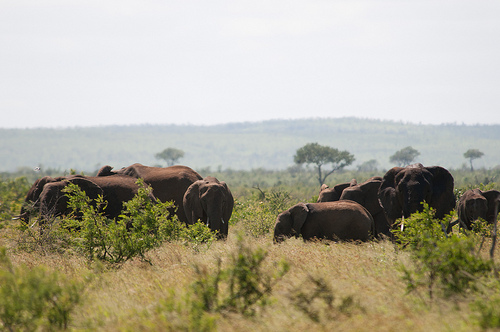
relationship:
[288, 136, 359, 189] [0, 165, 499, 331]
tree on savannah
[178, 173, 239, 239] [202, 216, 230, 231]
elephant has tusk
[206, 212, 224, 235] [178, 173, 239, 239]
trunk of elephant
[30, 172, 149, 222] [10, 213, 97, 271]
elephant eating food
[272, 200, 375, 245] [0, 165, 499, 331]
elephant in a field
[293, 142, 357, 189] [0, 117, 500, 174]
tree in distance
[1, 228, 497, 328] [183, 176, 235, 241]
plants near elephant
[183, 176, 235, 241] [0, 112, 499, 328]
elephant grazing in africa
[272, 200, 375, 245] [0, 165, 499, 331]
elephant in natural habitat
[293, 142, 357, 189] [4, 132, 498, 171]
tree in distance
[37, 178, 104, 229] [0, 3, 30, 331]
elephant facing left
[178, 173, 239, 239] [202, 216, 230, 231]
elephant has white tusks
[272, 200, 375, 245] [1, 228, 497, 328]
elephant graze on shrubs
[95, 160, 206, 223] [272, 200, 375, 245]
elephant in a elephant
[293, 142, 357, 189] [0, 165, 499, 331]
tree on flat land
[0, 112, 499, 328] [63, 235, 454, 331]
landscape has dry vegetation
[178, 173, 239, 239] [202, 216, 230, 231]
elephant with tusks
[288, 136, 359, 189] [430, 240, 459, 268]
tree has leaves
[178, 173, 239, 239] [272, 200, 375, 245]
elephant in elephant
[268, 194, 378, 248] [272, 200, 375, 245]
elephant in elephant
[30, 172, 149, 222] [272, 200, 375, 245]
elephant in elephant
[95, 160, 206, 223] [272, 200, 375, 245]
elephant in elephant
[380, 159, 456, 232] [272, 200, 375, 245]
elephant in elephant